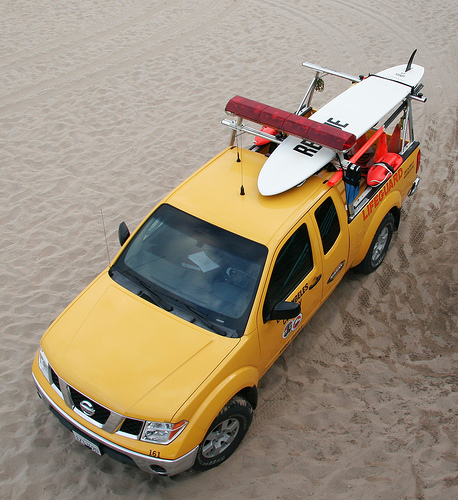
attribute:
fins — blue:
[345, 177, 358, 211]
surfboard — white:
[245, 32, 428, 200]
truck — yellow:
[26, 82, 429, 492]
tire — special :
[358, 212, 400, 275]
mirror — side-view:
[271, 300, 310, 321]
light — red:
[224, 92, 358, 168]